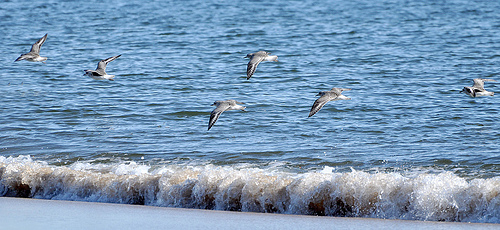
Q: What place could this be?
A: It is an ocean.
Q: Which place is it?
A: It is an ocean.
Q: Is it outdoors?
A: Yes, it is outdoors.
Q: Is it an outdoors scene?
A: Yes, it is outdoors.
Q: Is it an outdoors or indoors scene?
A: It is outdoors.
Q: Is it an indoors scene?
A: No, it is outdoors.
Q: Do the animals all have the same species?
A: Yes, all the animals are birds.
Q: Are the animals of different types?
A: No, all the animals are birds.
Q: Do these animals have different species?
A: No, all the animals are birds.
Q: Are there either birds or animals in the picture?
A: Yes, there is a bird.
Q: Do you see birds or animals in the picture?
A: Yes, there is a bird.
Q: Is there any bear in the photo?
A: No, there are no bears.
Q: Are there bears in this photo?
A: No, there are no bears.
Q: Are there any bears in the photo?
A: No, there are no bears.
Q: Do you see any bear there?
A: No, there are no bears.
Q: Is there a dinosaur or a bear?
A: No, there are no bears or dinosaurs.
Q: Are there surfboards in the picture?
A: No, there are no surfboards.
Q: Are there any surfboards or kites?
A: No, there are no surfboards or kites.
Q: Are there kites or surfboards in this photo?
A: No, there are no surfboards or kites.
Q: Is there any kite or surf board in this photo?
A: No, there are no surfboards or kites.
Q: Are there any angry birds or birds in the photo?
A: Yes, there is a bird.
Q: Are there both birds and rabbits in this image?
A: No, there is a bird but no rabbits.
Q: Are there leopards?
A: No, there are no leopards.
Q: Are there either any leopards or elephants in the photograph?
A: No, there are no leopards or elephants.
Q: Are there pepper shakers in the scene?
A: No, there are no pepper shakers.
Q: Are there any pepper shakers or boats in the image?
A: No, there are no pepper shakers or boats.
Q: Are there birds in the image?
A: Yes, there is a bird.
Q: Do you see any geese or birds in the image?
A: Yes, there is a bird.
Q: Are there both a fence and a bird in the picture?
A: No, there is a bird but no fences.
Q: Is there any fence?
A: No, there are no fences.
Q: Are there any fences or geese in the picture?
A: No, there are no fences or geese.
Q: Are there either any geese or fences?
A: No, there are no fences or geese.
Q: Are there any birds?
A: Yes, there is a bird.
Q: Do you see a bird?
A: Yes, there is a bird.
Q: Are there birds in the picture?
A: Yes, there is a bird.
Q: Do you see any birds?
A: Yes, there is a bird.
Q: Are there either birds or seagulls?
A: Yes, there is a bird.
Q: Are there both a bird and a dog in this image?
A: No, there is a bird but no dogs.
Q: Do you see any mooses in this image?
A: No, there are no mooses.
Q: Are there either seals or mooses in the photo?
A: No, there are no mooses or seals.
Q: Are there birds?
A: Yes, there is a bird.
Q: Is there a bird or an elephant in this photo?
A: Yes, there is a bird.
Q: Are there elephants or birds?
A: Yes, there is a bird.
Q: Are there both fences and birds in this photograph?
A: No, there is a bird but no fences.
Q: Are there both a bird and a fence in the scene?
A: No, there is a bird but no fences.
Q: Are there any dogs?
A: No, there are no dogs.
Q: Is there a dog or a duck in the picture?
A: No, there are no dogs or ducks.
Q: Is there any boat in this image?
A: No, there are no boats.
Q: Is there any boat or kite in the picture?
A: No, there are no boats or kites.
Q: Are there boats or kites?
A: No, there are no boats or kites.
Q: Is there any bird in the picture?
A: Yes, there is a bird.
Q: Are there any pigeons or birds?
A: Yes, there is a bird.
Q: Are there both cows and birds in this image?
A: No, there is a bird but no cows.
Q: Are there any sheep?
A: No, there are no sheep.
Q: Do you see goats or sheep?
A: No, there are no sheep or goats.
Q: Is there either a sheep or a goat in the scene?
A: No, there are no sheep or goats.